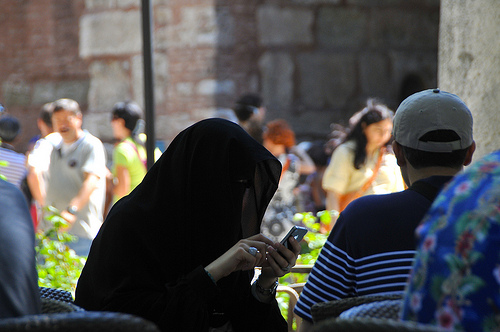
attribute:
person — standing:
[32, 95, 107, 257]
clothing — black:
[74, 116, 292, 330]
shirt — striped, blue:
[287, 173, 450, 309]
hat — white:
[390, 87, 484, 151]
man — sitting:
[284, 76, 482, 327]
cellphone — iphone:
[282, 222, 310, 244]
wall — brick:
[7, 2, 433, 144]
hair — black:
[335, 103, 393, 169]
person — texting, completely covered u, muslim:
[81, 113, 301, 325]